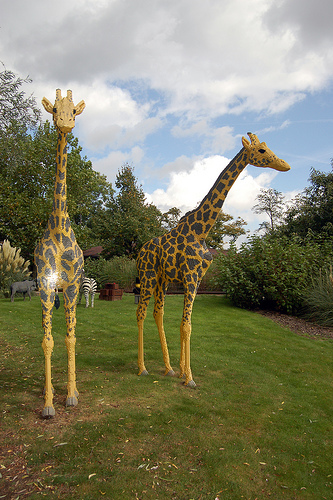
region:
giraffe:
[26, 80, 91, 420]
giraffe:
[142, 132, 294, 389]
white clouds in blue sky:
[112, 30, 156, 73]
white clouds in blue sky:
[132, 55, 165, 84]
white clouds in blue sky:
[198, 64, 232, 79]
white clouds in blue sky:
[82, 51, 121, 106]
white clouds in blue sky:
[183, 81, 216, 126]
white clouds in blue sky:
[241, 34, 284, 67]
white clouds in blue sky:
[106, 34, 136, 86]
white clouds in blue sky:
[90, 1, 143, 71]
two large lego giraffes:
[40, 92, 288, 298]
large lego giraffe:
[33, 88, 93, 350]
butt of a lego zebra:
[85, 277, 99, 306]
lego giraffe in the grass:
[149, 140, 300, 355]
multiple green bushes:
[248, 217, 324, 305]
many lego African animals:
[45, 90, 256, 359]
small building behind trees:
[80, 233, 122, 271]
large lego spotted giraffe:
[165, 122, 265, 347]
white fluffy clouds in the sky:
[101, 98, 225, 152]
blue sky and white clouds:
[75, 45, 322, 161]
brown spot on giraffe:
[240, 153, 248, 163]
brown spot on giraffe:
[236, 155, 243, 163]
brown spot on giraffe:
[213, 198, 222, 210]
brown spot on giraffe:
[200, 237, 208, 251]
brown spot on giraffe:
[185, 273, 193, 282]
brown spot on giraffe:
[190, 273, 197, 282]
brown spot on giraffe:
[188, 282, 195, 291]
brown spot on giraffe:
[187, 292, 192, 301]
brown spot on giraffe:
[65, 281, 77, 302]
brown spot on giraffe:
[38, 288, 47, 303]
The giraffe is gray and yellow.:
[22, 66, 96, 423]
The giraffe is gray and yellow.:
[123, 121, 297, 386]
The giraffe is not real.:
[20, 79, 105, 423]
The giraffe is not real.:
[127, 126, 295, 390]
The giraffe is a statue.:
[31, 84, 88, 426]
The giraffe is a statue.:
[126, 127, 295, 390]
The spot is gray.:
[175, 233, 186, 245]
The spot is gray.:
[185, 255, 201, 271]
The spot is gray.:
[144, 259, 153, 271]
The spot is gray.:
[184, 270, 193, 284]